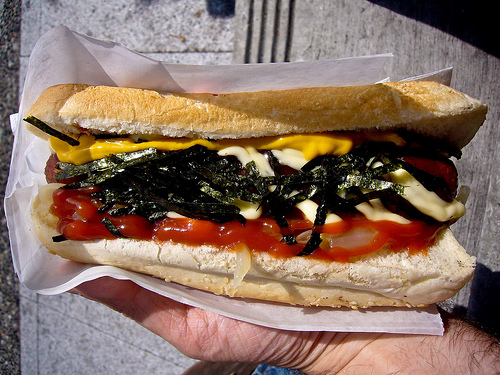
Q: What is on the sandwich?
A: Ketchp.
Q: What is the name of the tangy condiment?
A: Mustard.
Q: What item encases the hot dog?
A: Bun.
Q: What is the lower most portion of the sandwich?
A: Bottom bread.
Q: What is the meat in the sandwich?
A: Hot dog.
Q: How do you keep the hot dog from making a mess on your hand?
A: The wrapper.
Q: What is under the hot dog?
A: A wrapper.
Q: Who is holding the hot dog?
A: A man.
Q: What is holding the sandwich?
A: Hand.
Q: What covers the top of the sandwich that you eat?
A: Bread.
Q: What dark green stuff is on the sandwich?
A: Spinach.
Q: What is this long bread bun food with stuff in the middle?
A: Hotodg.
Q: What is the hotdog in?
A: Bun.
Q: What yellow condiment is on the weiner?
A: Mustard.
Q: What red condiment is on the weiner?
A: Ketchup.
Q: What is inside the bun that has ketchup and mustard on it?
A: Hotdog.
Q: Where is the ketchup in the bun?
A: On top of the hotdog.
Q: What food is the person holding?
A: A hotdog.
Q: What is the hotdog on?
A: A napkin.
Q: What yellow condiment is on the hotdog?
A: Mustard.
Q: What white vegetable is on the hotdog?
A: An onion.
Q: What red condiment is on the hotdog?
A: Ketchup.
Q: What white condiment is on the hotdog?
A: Mayo.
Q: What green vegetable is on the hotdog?
A: Seaweed.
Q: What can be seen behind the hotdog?
A: The ground.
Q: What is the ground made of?
A: Cement.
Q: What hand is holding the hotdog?
A: The left hand.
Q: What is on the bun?
A: Seaweed.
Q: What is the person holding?
A: Sandwich.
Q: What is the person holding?
A: Sandwich.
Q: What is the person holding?
A: Sandwich.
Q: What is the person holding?
A: Sandwich.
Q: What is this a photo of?
A: A hot dog.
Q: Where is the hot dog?
A: In the man's hand.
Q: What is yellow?
A: The mustard.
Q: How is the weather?
A: Sunny.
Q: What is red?
A: Ketchup.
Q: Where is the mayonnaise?
A: On top of the hot dog.